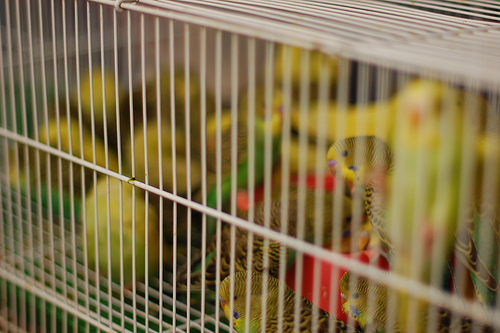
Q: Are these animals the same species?
A: No, there are both giraffes and birds.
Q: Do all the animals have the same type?
A: No, there are both giraffes and birds.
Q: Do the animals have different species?
A: Yes, they are giraffes and birds.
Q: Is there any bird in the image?
A: Yes, there are birds.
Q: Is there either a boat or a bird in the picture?
A: Yes, there are birds.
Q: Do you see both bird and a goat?
A: No, there are birds but no goats.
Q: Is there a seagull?
A: No, there are no seagulls.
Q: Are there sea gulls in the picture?
A: No, there are no sea gulls.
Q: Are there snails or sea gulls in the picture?
A: No, there are no sea gulls or snails.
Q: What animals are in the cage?
A: The animals are birds.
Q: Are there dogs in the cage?
A: No, there are birds in the cage.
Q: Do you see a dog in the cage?
A: No, there are birds in the cage.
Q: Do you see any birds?
A: Yes, there are birds.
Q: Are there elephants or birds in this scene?
A: Yes, there are birds.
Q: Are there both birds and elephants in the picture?
A: No, there are birds but no elephants.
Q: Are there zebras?
A: No, there are no zebras.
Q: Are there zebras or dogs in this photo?
A: No, there are no zebras or dogs.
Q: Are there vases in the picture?
A: No, there are no vases.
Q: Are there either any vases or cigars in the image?
A: No, there are no vases or cigars.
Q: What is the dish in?
A: The dish is in the cage.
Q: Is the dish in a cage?
A: Yes, the dish is in a cage.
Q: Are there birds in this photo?
A: Yes, there is a bird.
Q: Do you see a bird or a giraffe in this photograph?
A: Yes, there is a bird.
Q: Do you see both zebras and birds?
A: No, there is a bird but no zebras.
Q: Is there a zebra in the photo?
A: No, there are no zebras.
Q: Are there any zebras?
A: No, there are no zebras.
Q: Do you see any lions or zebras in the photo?
A: No, there are no zebras or lions.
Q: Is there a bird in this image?
A: Yes, there is a bird.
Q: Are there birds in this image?
A: Yes, there is a bird.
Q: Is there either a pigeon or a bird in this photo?
A: Yes, there is a bird.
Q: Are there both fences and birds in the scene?
A: No, there is a bird but no fences.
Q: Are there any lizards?
A: No, there are no lizards.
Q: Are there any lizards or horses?
A: No, there are no lizards or horses.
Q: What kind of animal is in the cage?
A: The animal is a bird.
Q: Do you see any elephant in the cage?
A: No, there is a bird in the cage.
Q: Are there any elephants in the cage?
A: No, there is a bird in the cage.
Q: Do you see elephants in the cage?
A: No, there is a bird in the cage.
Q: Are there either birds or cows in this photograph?
A: Yes, there are birds.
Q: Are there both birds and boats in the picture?
A: No, there are birds but no boats.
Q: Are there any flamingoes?
A: No, there are no flamingoes.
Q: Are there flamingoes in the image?
A: No, there are no flamingoes.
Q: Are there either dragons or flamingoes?
A: No, there are no flamingoes or dragons.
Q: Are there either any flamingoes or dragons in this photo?
A: No, there are no flamingoes or dragons.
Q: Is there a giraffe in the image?
A: Yes, there is a giraffe.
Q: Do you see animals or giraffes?
A: Yes, there is a giraffe.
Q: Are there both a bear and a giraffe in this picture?
A: No, there is a giraffe but no bears.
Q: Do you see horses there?
A: No, there are no horses.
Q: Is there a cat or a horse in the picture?
A: No, there are no horses or cats.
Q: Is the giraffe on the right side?
A: Yes, the giraffe is on the right of the image.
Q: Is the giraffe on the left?
A: No, the giraffe is on the right of the image.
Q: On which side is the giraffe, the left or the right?
A: The giraffe is on the right of the image.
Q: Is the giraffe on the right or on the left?
A: The giraffe is on the right of the image.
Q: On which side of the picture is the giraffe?
A: The giraffe is on the right of the image.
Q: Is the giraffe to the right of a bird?
A: Yes, the giraffe is to the right of a bird.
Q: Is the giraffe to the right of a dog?
A: No, the giraffe is to the right of a bird.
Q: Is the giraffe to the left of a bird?
A: No, the giraffe is to the right of a bird.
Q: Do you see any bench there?
A: No, there are no benches.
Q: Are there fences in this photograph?
A: No, there are no fences.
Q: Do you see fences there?
A: No, there are no fences.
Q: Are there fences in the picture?
A: No, there are no fences.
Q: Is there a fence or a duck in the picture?
A: No, there are no fences or ducks.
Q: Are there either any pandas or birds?
A: Yes, there is a bird.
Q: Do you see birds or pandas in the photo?
A: Yes, there is a bird.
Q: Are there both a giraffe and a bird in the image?
A: Yes, there are both a bird and a giraffe.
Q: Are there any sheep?
A: No, there are no sheep.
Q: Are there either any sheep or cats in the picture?
A: No, there are no sheep or cats.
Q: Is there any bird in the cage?
A: Yes, there is a bird in the cage.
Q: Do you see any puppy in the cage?
A: No, there is a bird in the cage.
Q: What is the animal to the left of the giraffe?
A: The animal is a bird.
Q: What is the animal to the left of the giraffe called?
A: The animal is a bird.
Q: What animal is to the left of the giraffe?
A: The animal is a bird.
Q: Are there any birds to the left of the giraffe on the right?
A: Yes, there is a bird to the left of the giraffe.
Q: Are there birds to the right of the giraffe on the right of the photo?
A: No, the bird is to the left of the giraffe.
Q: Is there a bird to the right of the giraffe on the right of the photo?
A: No, the bird is to the left of the giraffe.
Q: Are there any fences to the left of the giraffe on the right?
A: No, there is a bird to the left of the giraffe.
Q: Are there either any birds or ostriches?
A: Yes, there are birds.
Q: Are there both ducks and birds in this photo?
A: No, there are birds but no ducks.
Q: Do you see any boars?
A: No, there are no boars.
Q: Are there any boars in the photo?
A: No, there are no boars.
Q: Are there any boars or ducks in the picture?
A: No, there are no boars or ducks.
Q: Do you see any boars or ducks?
A: No, there are no boars or ducks.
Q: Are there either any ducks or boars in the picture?
A: No, there are no boars or ducks.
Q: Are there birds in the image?
A: Yes, there is a bird.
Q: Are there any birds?
A: Yes, there is a bird.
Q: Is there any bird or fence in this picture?
A: Yes, there is a bird.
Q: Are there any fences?
A: No, there are no fences.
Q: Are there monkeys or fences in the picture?
A: No, there are no fences or monkeys.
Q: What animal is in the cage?
A: The animal is a bird.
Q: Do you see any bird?
A: Yes, there is a bird.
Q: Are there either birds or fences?
A: Yes, there is a bird.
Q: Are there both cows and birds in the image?
A: No, there is a bird but no cows.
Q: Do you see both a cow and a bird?
A: No, there is a bird but no cows.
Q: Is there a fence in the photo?
A: No, there are no fences.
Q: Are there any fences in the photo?
A: No, there are no fences.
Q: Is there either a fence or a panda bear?
A: No, there are no fences or pandas.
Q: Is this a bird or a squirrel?
A: This is a bird.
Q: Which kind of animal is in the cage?
A: The animal is a bird.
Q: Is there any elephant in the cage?
A: No, there is a bird in the cage.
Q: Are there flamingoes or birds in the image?
A: Yes, there is a bird.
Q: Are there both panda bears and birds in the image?
A: No, there is a bird but no pandas.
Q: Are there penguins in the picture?
A: No, there are no penguins.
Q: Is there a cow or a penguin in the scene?
A: No, there are no penguins or cows.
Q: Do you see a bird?
A: Yes, there is a bird.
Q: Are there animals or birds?
A: Yes, there is a bird.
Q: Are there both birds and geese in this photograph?
A: No, there is a bird but no geese.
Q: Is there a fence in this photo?
A: No, there are no fences.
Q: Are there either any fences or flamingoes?
A: No, there are no fences or flamingoes.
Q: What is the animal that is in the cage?
A: The animal is a bird.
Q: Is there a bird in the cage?
A: Yes, there is a bird in the cage.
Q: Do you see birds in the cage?
A: Yes, there is a bird in the cage.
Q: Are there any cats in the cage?
A: No, there is a bird in the cage.